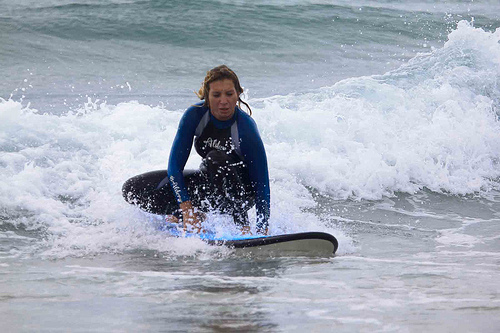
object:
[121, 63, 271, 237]
woman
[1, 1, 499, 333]
ocean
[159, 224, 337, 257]
surfboard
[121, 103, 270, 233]
wetsuit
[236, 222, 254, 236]
feet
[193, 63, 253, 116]
hair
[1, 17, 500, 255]
foam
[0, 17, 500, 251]
wave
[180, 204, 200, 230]
hands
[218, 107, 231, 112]
mouth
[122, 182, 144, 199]
knees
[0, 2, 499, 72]
ripples